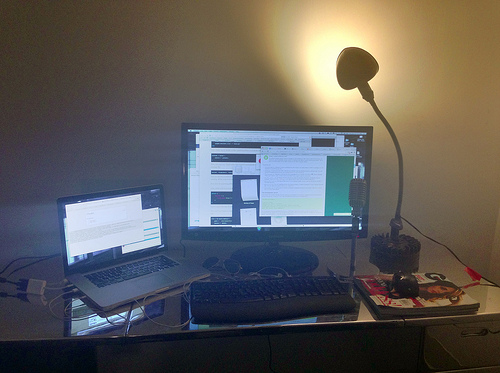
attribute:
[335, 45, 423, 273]
light — reflecting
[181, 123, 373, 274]
monitor — large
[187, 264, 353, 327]
computer keyboard — black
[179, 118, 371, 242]
monitor — open, computer, big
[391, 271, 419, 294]
mouse — magazine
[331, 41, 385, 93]
lamp — electric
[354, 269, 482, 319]
magazine — stack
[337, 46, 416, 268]
lamp — desk lamp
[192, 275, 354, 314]
keyboard — black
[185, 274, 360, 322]
keyboard — black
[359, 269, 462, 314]
magazines — small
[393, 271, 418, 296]
mouse — computer mouse, black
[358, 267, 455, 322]
magazines — pile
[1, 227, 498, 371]
desk — glass top desk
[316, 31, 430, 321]
lamp — black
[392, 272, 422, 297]
computer mouse — black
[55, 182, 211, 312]
laptop — silver, black, small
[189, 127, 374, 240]
screen — black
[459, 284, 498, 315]
desk — mirrored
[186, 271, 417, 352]
keyboard — black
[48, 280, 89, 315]
cords — several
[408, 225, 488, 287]
black cord — black 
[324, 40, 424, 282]
lamp — tall, desk lamp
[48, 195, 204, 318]
laptop — open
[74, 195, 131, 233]
screen — display